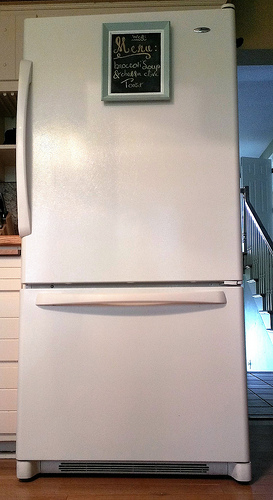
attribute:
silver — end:
[194, 28, 211, 32]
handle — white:
[36, 291, 227, 305]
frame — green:
[97, 19, 177, 105]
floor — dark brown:
[130, 467, 186, 495]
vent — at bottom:
[58, 463, 210, 472]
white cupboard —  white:
[1, 0, 222, 92]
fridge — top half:
[15, 3, 250, 482]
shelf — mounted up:
[1, 6, 19, 89]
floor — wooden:
[44, 477, 227, 499]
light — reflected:
[246, 316, 269, 370]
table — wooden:
[0, 227, 16, 243]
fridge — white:
[25, 22, 251, 447]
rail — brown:
[240, 184, 272, 250]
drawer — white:
[0, 259, 22, 289]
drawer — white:
[0, 299, 19, 362]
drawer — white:
[0, 368, 18, 434]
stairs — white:
[243, 244, 270, 372]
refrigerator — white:
[15, 2, 252, 482]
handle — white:
[14, 60, 37, 239]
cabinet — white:
[1, 17, 27, 73]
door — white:
[34, 62, 262, 270]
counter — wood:
[0, 235, 22, 253]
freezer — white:
[13, 282, 254, 469]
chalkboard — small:
[96, 17, 176, 106]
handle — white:
[29, 285, 235, 310]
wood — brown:
[0, 471, 242, 496]